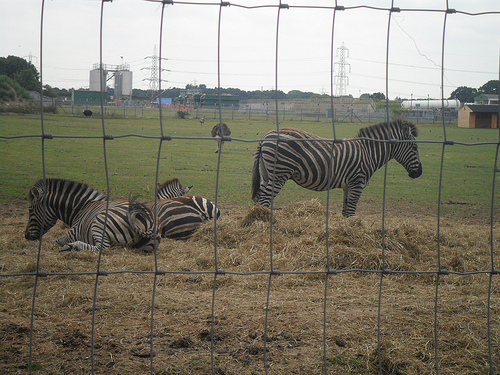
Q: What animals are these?
A: Zebras.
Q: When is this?
A: Daytime.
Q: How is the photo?
A: Clear.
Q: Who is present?
A: Nobody.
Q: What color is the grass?
A: Green.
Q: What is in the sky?
A: Nothing.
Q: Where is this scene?
A: In a zoo.